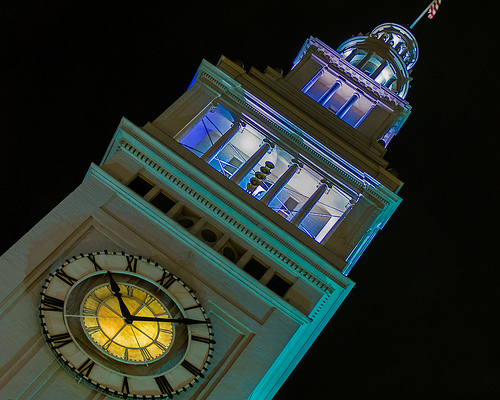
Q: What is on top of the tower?
A: Flag.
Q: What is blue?
A: Lights.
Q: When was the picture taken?
A: Nighttime.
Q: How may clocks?
A: One.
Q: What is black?
A: Sky.